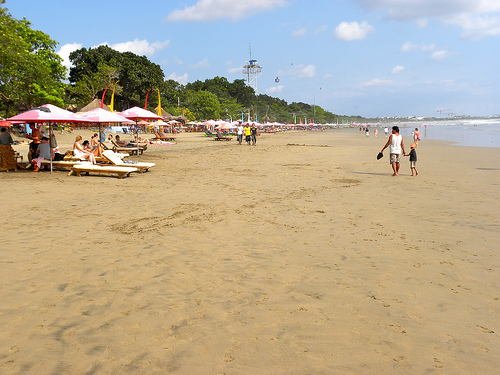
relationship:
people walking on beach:
[236, 122, 259, 146] [2, 116, 495, 373]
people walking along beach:
[234, 120, 262, 146] [15, 127, 483, 365]